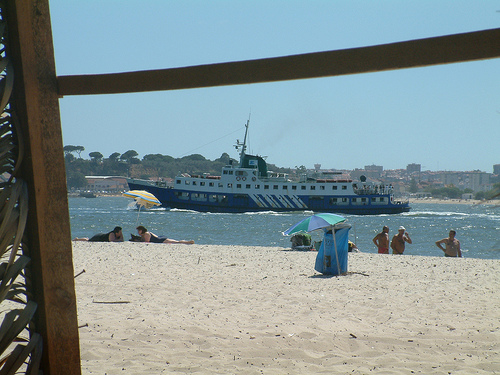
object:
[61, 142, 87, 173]
trees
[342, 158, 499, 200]
city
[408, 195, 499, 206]
beach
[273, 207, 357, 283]
umbrella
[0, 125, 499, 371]
scene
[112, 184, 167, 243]
umbrella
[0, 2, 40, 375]
plant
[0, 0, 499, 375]
window frame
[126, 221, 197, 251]
person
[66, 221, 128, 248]
person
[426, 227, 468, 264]
man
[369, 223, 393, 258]
man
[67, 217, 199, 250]
two peoples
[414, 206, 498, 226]
surf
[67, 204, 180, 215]
surf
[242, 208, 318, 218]
surf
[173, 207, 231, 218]
wave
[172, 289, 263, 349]
ground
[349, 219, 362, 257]
pole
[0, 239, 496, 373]
beach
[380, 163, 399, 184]
buildings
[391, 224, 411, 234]
hat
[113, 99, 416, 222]
cruise ship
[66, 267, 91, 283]
nail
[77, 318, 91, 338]
nail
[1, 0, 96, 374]
casing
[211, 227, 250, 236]
water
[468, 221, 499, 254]
water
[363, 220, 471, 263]
three men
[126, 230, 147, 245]
pillow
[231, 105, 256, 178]
mast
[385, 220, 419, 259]
man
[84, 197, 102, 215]
water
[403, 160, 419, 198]
building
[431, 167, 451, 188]
building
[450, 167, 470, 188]
building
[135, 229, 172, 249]
suit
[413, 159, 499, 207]
background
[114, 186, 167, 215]
piping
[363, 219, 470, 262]
group